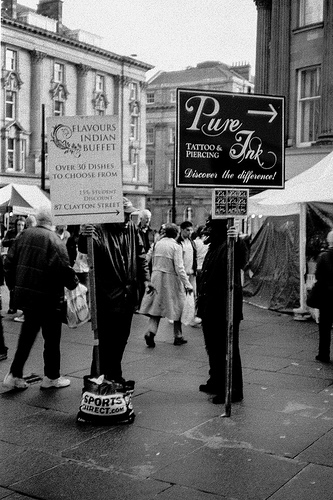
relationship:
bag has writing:
[70, 375, 175, 445] [73, 390, 113, 407]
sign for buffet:
[40, 100, 123, 208] [262, 225, 328, 302]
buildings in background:
[21, 14, 230, 105] [37, 8, 316, 170]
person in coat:
[149, 225, 204, 348] [159, 243, 196, 333]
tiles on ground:
[76, 431, 206, 464] [51, 417, 257, 478]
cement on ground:
[28, 412, 132, 482] [51, 417, 257, 478]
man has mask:
[181, 196, 289, 429] [174, 223, 246, 263]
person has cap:
[75, 210, 137, 388] [106, 194, 168, 230]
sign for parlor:
[162, 80, 271, 175] [286, 296, 329, 398]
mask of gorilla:
[174, 223, 246, 263] [175, 207, 243, 358]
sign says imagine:
[162, 80, 271, 175] [182, 159, 223, 187]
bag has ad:
[70, 375, 175, 445] [94, 391, 216, 448]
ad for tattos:
[94, 391, 216, 448] [174, 129, 209, 187]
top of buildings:
[29, 10, 148, 64] [21, 14, 230, 105]